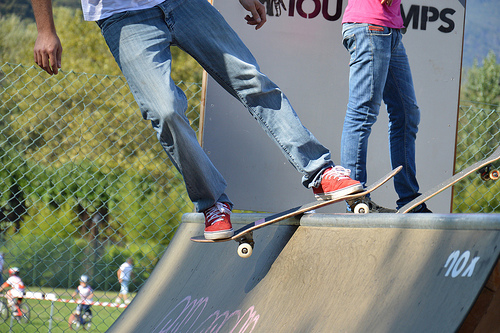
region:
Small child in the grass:
[65, 261, 93, 331]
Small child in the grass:
[98, 246, 131, 326]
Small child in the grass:
[1, 256, 33, 331]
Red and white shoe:
[174, 196, 244, 247]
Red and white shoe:
[291, 166, 366, 218]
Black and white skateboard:
[147, 174, 399, 276]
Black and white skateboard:
[380, 132, 495, 235]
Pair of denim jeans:
[58, 3, 372, 232]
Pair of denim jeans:
[312, 16, 437, 228]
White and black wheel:
[235, 242, 253, 267]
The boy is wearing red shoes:
[139, 156, 494, 262]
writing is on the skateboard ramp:
[129, 214, 496, 308]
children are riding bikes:
[3, 251, 189, 328]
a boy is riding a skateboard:
[167, 124, 497, 216]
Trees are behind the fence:
[4, 33, 254, 310]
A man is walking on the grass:
[49, 226, 267, 317]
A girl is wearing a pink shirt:
[339, 4, 459, 96]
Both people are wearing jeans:
[94, 33, 491, 234]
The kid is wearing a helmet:
[2, 263, 53, 322]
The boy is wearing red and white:
[2, 270, 35, 325]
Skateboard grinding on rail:
[161, 155, 407, 257]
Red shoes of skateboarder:
[192, 153, 359, 256]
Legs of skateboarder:
[91, 1, 371, 211]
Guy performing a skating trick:
[1, 1, 356, 250]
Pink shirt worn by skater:
[339, 0, 421, 25]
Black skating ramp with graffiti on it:
[109, 213, 499, 325]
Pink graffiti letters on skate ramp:
[152, 292, 267, 332]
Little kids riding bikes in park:
[4, 256, 99, 331]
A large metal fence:
[1, 60, 498, 331]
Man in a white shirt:
[108, 253, 135, 303]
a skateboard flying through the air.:
[189, 149, 407, 256]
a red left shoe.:
[307, 156, 377, 210]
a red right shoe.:
[200, 199, 241, 254]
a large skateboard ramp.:
[101, 211, 497, 331]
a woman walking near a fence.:
[109, 254, 146, 313]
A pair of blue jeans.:
[89, 0, 335, 217]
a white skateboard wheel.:
[343, 198, 373, 226]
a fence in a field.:
[1, 243, 171, 330]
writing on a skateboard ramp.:
[433, 239, 481, 293]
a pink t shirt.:
[340, 0, 412, 28]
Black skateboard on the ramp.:
[177, 163, 409, 256]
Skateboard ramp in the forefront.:
[91, 200, 496, 330]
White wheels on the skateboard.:
[235, 200, 367, 260]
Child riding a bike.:
[67, 271, 96, 328]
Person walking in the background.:
[115, 254, 130, 306]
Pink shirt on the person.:
[335, 0, 428, 220]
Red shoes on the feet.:
[176, 164, 363, 243]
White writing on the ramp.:
[438, 242, 480, 282]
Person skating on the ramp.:
[29, 0, 405, 266]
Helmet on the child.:
[5, 265, 24, 280]